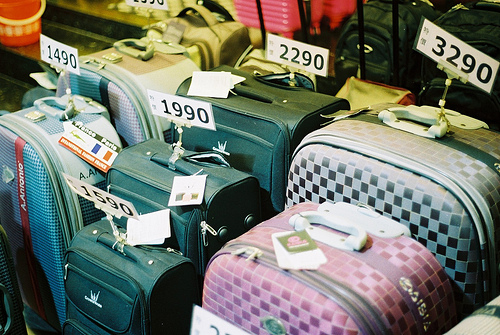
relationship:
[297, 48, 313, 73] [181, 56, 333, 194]
9 over black luggage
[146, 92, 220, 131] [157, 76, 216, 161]
sign says 1990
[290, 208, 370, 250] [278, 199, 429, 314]
handle on top luggage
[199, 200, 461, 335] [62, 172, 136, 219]
luggage under number 1590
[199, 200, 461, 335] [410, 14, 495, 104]
luggage under number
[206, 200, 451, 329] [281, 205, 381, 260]
luggage with handles